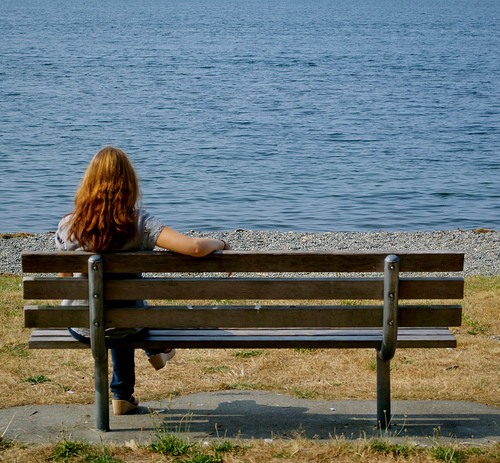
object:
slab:
[0, 383, 500, 449]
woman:
[50, 145, 228, 415]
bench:
[20, 250, 463, 432]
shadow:
[110, 401, 500, 441]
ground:
[0, 230, 498, 460]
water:
[0, 3, 500, 236]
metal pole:
[376, 353, 391, 428]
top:
[54, 207, 165, 340]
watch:
[219, 239, 227, 250]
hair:
[62, 146, 141, 251]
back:
[20, 251, 462, 330]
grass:
[0, 265, 500, 460]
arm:
[148, 217, 223, 260]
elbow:
[189, 237, 209, 257]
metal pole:
[91, 362, 111, 431]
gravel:
[452, 239, 459, 243]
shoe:
[112, 394, 140, 415]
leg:
[109, 347, 140, 416]